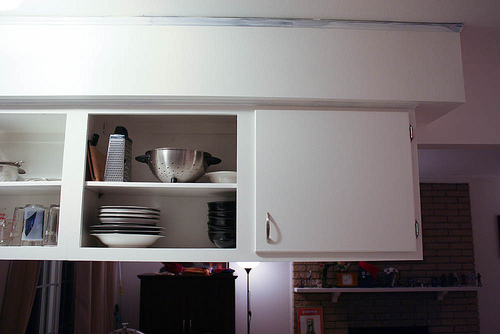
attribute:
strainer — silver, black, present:
[134, 146, 221, 183]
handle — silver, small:
[265, 213, 271, 243]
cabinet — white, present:
[237, 107, 425, 261]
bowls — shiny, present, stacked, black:
[206, 201, 234, 247]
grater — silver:
[101, 127, 131, 181]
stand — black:
[245, 267, 252, 334]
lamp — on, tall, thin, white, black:
[236, 261, 258, 270]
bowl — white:
[205, 171, 236, 184]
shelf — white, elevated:
[85, 181, 236, 200]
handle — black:
[136, 154, 149, 163]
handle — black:
[205, 156, 221, 166]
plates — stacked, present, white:
[87, 205, 166, 246]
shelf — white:
[292, 285, 489, 302]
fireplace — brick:
[347, 327, 436, 334]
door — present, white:
[253, 110, 417, 254]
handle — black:
[112, 125, 127, 135]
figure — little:
[476, 272, 483, 286]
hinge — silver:
[409, 123, 415, 141]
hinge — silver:
[414, 221, 420, 238]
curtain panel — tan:
[73, 261, 116, 333]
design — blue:
[22, 206, 44, 241]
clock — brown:
[337, 270, 358, 285]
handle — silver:
[187, 319, 194, 331]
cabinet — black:
[136, 273, 238, 333]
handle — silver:
[179, 318, 187, 333]